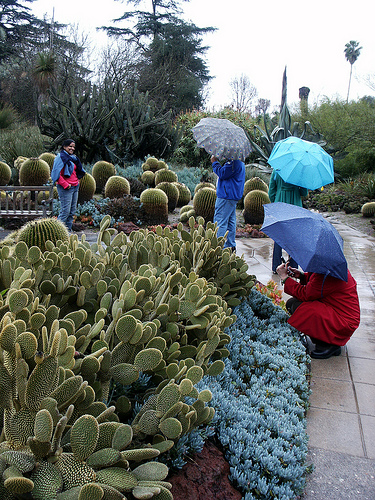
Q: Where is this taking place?
A: Outdoors.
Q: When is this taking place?
A: Daytime.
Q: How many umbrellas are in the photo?
A: Three.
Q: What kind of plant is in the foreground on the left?
A: Cactus.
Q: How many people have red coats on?
A: One.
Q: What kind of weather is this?
A: Rain.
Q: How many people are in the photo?
A: Four.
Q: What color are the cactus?
A: Green.